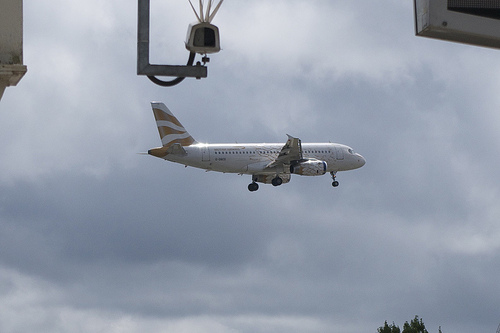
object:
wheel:
[332, 181, 339, 187]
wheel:
[247, 183, 258, 192]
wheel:
[272, 177, 283, 186]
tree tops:
[375, 314, 441, 333]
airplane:
[136, 101, 367, 192]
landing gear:
[330, 171, 340, 187]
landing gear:
[271, 175, 282, 186]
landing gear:
[246, 179, 258, 192]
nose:
[357, 154, 366, 169]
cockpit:
[344, 145, 355, 157]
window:
[259, 151, 262, 153]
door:
[202, 146, 210, 161]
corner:
[412, 15, 434, 37]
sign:
[413, 0, 500, 50]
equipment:
[180, 0, 231, 54]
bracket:
[136, 0, 208, 80]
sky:
[0, 0, 499, 333]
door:
[335, 146, 344, 160]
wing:
[265, 133, 303, 168]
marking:
[148, 107, 195, 157]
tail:
[149, 101, 197, 147]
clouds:
[47, 2, 498, 94]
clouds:
[5, 211, 498, 306]